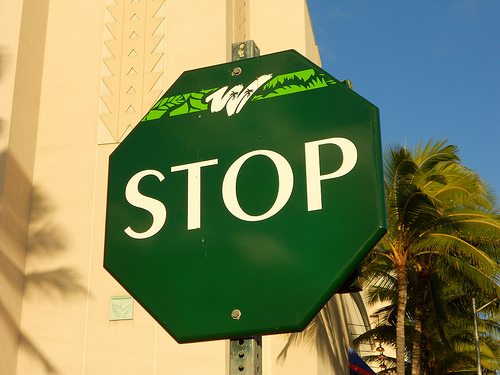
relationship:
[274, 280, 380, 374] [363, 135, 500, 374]
shadow from tree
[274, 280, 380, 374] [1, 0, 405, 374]
shadow on building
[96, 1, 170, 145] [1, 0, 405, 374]
design on building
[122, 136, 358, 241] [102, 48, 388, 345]
lettering on sign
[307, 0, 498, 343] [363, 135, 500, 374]
sky above tree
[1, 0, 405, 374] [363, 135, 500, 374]
building next to tree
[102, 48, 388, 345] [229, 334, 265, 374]
sign on post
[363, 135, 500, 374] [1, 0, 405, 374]
tree next to building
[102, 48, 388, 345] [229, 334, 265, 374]
sign attached to post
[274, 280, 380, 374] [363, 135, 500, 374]
shadow of tree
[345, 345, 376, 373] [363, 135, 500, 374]
triangle next to tree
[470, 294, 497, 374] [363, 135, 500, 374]
light pole under tree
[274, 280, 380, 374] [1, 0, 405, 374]
shadow cast on building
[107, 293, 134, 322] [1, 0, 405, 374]
switch on building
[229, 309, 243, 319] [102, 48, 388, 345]
bolt on sign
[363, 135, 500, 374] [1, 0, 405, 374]
tree by building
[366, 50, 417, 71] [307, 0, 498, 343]
part of sky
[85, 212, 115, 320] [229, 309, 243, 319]
part of a bolt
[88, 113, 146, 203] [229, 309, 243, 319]
part of a bolt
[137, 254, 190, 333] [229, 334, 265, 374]
part of a post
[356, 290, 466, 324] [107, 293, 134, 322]
edge of a switch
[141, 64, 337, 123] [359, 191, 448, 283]
logo logo has palm trees